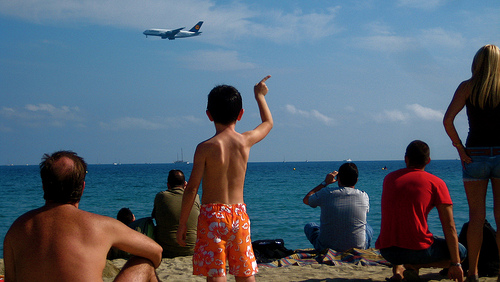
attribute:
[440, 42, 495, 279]
woman — blonde-haired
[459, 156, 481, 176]
pocket — back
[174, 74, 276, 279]
boy — little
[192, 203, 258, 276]
shorts — orange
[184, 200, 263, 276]
swimsuit — orange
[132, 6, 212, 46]
plane — passenger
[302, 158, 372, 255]
man — sitting 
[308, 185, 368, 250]
shirt — blue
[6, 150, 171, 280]
man — Shirtless , sitting 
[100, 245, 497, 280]
sand — sitting 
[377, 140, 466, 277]
man — sitting 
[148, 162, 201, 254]
man — sitting 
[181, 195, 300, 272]
shorts — orange, white, Hawaiian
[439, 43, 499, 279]
lady — standing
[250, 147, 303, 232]
water — calm, blue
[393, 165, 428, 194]
shirt — red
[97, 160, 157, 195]
water — blue, sea